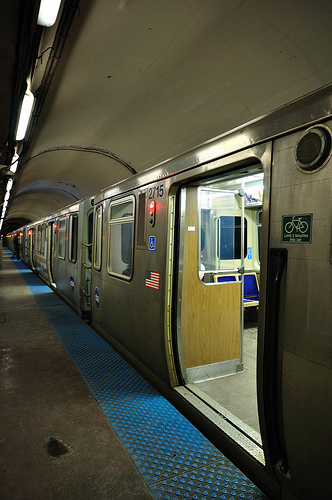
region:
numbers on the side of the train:
[142, 181, 168, 199]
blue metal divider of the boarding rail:
[92, 329, 154, 490]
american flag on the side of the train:
[138, 267, 165, 294]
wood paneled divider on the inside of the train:
[187, 187, 243, 375]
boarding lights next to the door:
[144, 199, 158, 225]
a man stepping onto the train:
[10, 227, 25, 265]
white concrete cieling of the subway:
[69, 49, 277, 121]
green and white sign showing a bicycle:
[277, 207, 318, 248]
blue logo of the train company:
[89, 282, 104, 318]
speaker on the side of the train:
[293, 121, 326, 179]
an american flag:
[142, 266, 161, 287]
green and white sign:
[280, 213, 314, 245]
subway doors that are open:
[159, 153, 264, 487]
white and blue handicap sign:
[146, 234, 156, 250]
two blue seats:
[216, 271, 262, 307]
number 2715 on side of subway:
[144, 183, 168, 200]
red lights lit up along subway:
[4, 197, 163, 238]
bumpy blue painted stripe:
[2, 243, 269, 499]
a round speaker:
[292, 121, 330, 174]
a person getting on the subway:
[9, 226, 29, 263]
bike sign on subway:
[280, 215, 312, 243]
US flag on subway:
[144, 270, 159, 290]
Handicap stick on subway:
[147, 234, 155, 250]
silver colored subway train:
[5, 82, 330, 498]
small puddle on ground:
[41, 437, 72, 461]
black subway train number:
[148, 184, 167, 200]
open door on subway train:
[166, 159, 260, 453]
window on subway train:
[106, 194, 135, 283]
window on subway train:
[93, 206, 101, 269]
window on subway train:
[55, 218, 66, 260]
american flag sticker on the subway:
[145, 267, 161, 290]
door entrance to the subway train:
[172, 154, 271, 469]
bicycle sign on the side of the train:
[280, 213, 312, 246]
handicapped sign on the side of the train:
[147, 235, 156, 250]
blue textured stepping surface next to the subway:
[5, 249, 269, 498]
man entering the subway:
[14, 232, 21, 261]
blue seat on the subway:
[214, 270, 262, 307]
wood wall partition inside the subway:
[181, 185, 242, 381]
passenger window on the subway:
[105, 194, 135, 284]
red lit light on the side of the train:
[149, 200, 154, 227]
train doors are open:
[18, 202, 286, 423]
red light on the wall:
[140, 193, 169, 241]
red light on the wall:
[45, 220, 66, 240]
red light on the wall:
[20, 226, 34, 241]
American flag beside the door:
[133, 269, 160, 291]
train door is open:
[139, 208, 272, 423]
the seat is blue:
[221, 268, 283, 334]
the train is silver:
[24, 210, 170, 374]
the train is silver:
[16, 217, 90, 308]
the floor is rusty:
[4, 328, 113, 471]